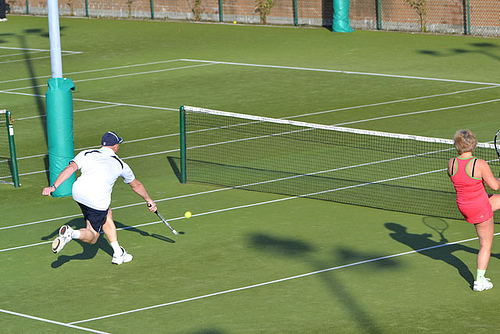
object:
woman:
[447, 128, 500, 292]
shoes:
[473, 278, 493, 291]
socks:
[476, 268, 487, 278]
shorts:
[77, 200, 113, 231]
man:
[42, 130, 157, 264]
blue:
[91, 214, 102, 224]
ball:
[184, 211, 191, 219]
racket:
[148, 204, 179, 235]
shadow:
[25, 28, 41, 33]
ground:
[103, 14, 143, 36]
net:
[178, 105, 500, 227]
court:
[0, 15, 500, 334]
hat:
[102, 130, 124, 146]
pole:
[179, 107, 186, 184]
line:
[73, 69, 157, 85]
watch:
[51, 184, 57, 189]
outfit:
[448, 157, 494, 224]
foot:
[51, 225, 73, 254]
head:
[102, 138, 119, 152]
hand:
[146, 200, 157, 212]